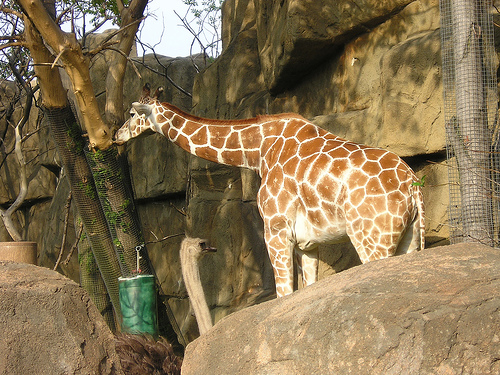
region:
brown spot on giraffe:
[362, 158, 381, 178]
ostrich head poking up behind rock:
[168, 222, 223, 272]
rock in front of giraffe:
[186, 268, 458, 370]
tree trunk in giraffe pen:
[108, 84, 146, 274]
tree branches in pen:
[40, 187, 82, 272]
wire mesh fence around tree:
[436, 88, 493, 263]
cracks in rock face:
[340, 304, 460, 374]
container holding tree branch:
[0, 227, 46, 269]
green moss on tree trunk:
[88, 172, 124, 242]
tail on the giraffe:
[403, 177, 430, 289]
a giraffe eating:
[115, 82, 427, 294]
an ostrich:
[116, 200, 229, 372]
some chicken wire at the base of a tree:
[435, 0, 496, 242]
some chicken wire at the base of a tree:
[90, 146, 200, 351]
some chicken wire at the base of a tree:
[31, 102, 121, 322]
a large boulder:
[182, 216, 492, 368]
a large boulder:
[5, 251, 110, 371]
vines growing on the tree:
[84, 150, 158, 270]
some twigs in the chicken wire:
[416, 115, 498, 240]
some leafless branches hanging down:
[26, 10, 233, 105]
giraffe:
[113, 90, 415, 247]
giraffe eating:
[102, 96, 417, 249]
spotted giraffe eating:
[105, 80, 389, 237]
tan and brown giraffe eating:
[107, 77, 414, 259]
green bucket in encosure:
[106, 272, 158, 326]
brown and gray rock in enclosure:
[255, 295, 457, 364]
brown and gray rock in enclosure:
[11, 298, 78, 360]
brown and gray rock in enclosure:
[254, 21, 416, 94]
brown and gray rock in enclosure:
[208, 205, 250, 287]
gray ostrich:
[166, 234, 220, 319]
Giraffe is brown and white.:
[223, 124, 398, 259]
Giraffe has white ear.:
[128, 95, 158, 115]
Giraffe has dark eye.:
[128, 107, 139, 121]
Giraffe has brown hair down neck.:
[156, 97, 256, 139]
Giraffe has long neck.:
[169, 102, 289, 211]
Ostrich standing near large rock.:
[158, 218, 255, 362]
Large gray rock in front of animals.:
[261, 288, 471, 358]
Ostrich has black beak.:
[200, 232, 218, 262]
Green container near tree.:
[109, 264, 209, 367]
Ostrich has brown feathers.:
[112, 328, 161, 364]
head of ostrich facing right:
[172, 232, 233, 310]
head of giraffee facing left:
[113, 99, 192, 156]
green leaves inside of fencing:
[83, 148, 170, 240]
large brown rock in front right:
[286, 275, 488, 369]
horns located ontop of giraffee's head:
[142, 73, 179, 103]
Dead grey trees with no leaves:
[8, 47, 73, 176]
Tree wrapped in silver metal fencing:
[432, 24, 498, 171]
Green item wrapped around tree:
[96, 267, 154, 350]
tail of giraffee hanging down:
[413, 183, 436, 270]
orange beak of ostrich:
[203, 243, 228, 270]